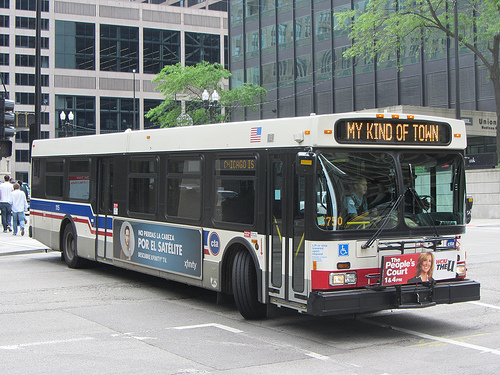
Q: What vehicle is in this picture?
A: A bus.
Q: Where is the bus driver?
A: In the front of the bus.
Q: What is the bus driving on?
A: A road.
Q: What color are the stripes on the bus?
A: Red and blus.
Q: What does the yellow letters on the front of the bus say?
A: My Kind of Town.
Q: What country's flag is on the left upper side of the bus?
A: United States.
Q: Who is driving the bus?
A: A bus driver.